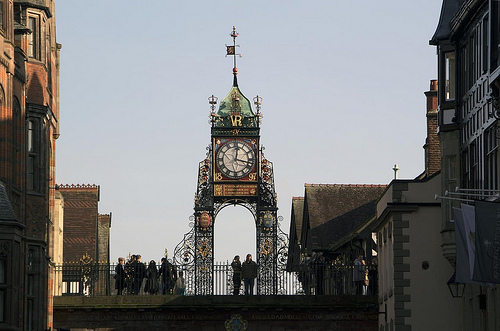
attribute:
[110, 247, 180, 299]
people — talking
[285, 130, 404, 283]
roof — dirty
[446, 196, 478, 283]
flag — white